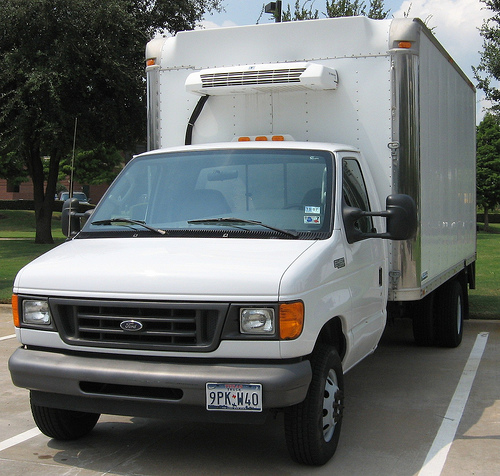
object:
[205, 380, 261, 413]
this is a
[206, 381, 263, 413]
plate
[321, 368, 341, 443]
rim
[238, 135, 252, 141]
this is a small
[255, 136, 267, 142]
this is a small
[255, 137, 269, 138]
light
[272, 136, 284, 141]
this is a small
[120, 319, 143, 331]
emblem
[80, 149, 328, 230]
windshield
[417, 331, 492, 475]
stripe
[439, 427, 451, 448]
is white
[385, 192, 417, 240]
these mirror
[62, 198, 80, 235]
mirror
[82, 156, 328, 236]
mirror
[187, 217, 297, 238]
this is a black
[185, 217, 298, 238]
wiper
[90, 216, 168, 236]
this is a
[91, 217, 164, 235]
wiper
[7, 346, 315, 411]
this is a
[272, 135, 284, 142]
this is headlight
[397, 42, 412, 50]
this is headlight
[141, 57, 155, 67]
this is headlight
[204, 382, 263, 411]
this license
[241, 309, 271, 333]
this light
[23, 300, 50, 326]
light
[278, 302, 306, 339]
these light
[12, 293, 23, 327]
these light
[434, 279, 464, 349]
these tire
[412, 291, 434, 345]
these tire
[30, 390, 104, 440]
these tire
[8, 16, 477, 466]
this truck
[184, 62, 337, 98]
vent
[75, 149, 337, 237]
these is front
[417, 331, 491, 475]
these line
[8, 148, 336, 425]
front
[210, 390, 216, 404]
this is a 9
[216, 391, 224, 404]
this a p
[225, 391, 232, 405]
this is a k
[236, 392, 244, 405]
this is a w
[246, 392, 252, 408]
this is a  4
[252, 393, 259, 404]
this is a 0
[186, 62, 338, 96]
on the truck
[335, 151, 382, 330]
this the door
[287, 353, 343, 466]
this tire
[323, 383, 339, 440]
this rim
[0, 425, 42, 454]
this stripe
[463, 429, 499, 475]
cement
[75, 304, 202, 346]
this grill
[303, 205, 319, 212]
these sticker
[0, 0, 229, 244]
this tree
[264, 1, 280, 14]
light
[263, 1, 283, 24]
in the top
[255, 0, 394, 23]
top tree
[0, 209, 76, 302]
these is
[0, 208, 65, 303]
in the grass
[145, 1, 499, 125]
this is blue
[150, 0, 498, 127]
sky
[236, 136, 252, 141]
headlight